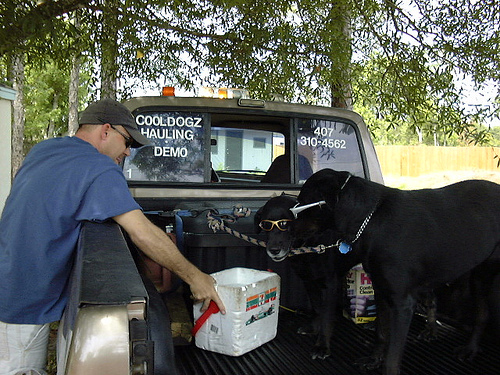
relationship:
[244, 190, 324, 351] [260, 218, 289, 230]
dog in glasses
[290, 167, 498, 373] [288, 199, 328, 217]
dog in sunglasses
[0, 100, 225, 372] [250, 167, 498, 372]
man near dogs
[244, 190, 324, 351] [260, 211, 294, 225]
dog has glasses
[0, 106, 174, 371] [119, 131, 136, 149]
man has sunglasses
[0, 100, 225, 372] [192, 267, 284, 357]
man has cooler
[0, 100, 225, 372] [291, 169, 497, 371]
man has dogs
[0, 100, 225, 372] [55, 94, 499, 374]
man leaning over truck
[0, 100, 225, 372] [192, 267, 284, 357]
man holding cooler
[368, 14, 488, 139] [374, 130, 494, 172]
tree behind fence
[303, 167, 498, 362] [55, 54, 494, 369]
dog standing in truck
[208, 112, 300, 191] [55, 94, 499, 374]
window on truck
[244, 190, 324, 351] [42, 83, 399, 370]
dog in truck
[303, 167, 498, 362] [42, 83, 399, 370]
dog in truck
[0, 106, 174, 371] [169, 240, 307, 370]
man holding cooler